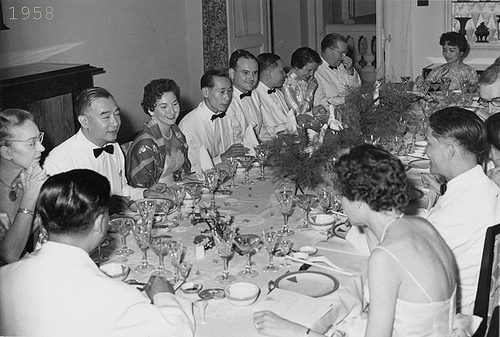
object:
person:
[42, 86, 169, 204]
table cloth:
[98, 82, 468, 336]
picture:
[1, 1, 499, 336]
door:
[321, 1, 393, 87]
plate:
[272, 271, 338, 297]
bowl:
[308, 213, 336, 232]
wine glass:
[273, 188, 297, 236]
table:
[39, 80, 499, 335]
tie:
[93, 145, 116, 159]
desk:
[0, 63, 106, 147]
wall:
[0, 1, 202, 137]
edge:
[331, 281, 341, 293]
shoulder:
[46, 131, 86, 162]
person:
[254, 140, 479, 337]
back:
[395, 217, 459, 331]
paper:
[252, 285, 335, 326]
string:
[375, 245, 432, 304]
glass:
[230, 233, 263, 281]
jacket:
[229, 86, 287, 143]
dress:
[365, 243, 484, 337]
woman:
[422, 31, 478, 92]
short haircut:
[72, 86, 115, 117]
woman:
[0, 106, 52, 264]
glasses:
[4, 134, 50, 149]